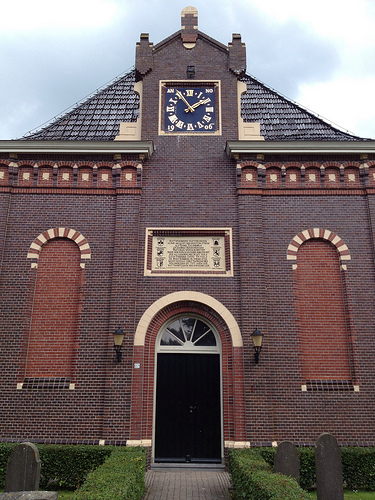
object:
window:
[154, 310, 223, 352]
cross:
[179, 11, 198, 30]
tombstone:
[311, 430, 345, 500]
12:
[183, 86, 194, 98]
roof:
[0, 4, 374, 139]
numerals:
[184, 87, 195, 98]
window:
[21, 227, 85, 382]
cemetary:
[0, 486, 77, 497]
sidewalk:
[143, 464, 233, 500]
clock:
[163, 80, 222, 141]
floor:
[147, 470, 230, 499]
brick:
[312, 386, 317, 393]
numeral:
[203, 103, 215, 115]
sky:
[1, 1, 131, 71]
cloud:
[0, 1, 131, 42]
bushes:
[0, 442, 148, 498]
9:
[166, 104, 175, 113]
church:
[0, 11, 375, 445]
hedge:
[0, 440, 148, 499]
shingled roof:
[14, 4, 367, 140]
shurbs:
[230, 447, 307, 497]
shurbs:
[50, 440, 153, 499]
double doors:
[153, 350, 221, 466]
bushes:
[220, 436, 375, 500]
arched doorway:
[128, 289, 245, 470]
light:
[111, 325, 126, 352]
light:
[249, 326, 265, 355]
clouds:
[279, 19, 365, 91]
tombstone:
[2, 438, 44, 491]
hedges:
[221, 442, 372, 499]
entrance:
[130, 290, 243, 468]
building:
[1, 5, 373, 500]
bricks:
[304, 274, 338, 336]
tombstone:
[272, 440, 302, 488]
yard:
[1, 435, 369, 500]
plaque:
[151, 236, 226, 269]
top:
[24, 225, 92, 269]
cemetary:
[1, 422, 374, 499]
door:
[150, 348, 229, 469]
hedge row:
[0, 433, 375, 499]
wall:
[0, 30, 375, 452]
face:
[165, 85, 215, 133]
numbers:
[184, 88, 195, 100]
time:
[158, 79, 221, 136]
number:
[186, 120, 195, 133]